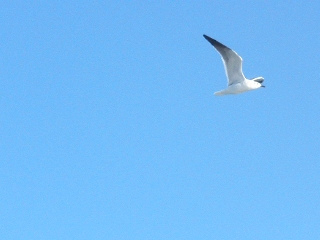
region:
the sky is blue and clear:
[19, 16, 232, 235]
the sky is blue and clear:
[40, 35, 150, 202]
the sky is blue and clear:
[76, 101, 136, 222]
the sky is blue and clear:
[139, 181, 160, 232]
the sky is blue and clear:
[104, 116, 168, 233]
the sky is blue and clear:
[114, 125, 149, 215]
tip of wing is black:
[200, 34, 228, 61]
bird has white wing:
[199, 24, 239, 88]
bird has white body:
[212, 78, 262, 102]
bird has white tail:
[215, 88, 234, 103]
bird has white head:
[248, 75, 261, 93]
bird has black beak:
[259, 83, 263, 88]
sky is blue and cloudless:
[7, 0, 49, 74]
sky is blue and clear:
[6, 4, 49, 79]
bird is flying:
[192, 34, 267, 99]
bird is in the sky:
[201, 34, 265, 100]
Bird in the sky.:
[191, 24, 269, 100]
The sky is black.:
[92, 144, 171, 196]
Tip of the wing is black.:
[200, 30, 232, 58]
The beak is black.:
[254, 80, 269, 92]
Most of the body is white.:
[216, 64, 257, 102]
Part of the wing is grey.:
[217, 49, 242, 73]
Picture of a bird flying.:
[1, 2, 319, 238]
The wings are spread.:
[196, 29, 273, 115]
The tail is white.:
[213, 82, 229, 101]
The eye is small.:
[249, 74, 269, 95]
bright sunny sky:
[5, 3, 195, 235]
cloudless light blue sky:
[3, 0, 196, 233]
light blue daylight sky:
[5, 3, 197, 227]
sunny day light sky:
[1, 2, 190, 231]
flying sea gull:
[187, 16, 274, 112]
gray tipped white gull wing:
[194, 27, 243, 78]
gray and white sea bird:
[185, 24, 269, 102]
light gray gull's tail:
[206, 80, 231, 112]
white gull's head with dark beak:
[246, 68, 265, 94]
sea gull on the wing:
[191, 26, 270, 105]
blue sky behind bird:
[166, 18, 288, 146]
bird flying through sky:
[176, 16, 295, 176]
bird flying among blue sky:
[165, 21, 282, 153]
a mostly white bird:
[176, 18, 288, 124]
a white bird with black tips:
[145, 16, 309, 148]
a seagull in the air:
[144, 16, 272, 119]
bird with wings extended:
[176, 16, 288, 115]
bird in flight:
[160, 16, 272, 128]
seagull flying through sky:
[146, 20, 265, 121]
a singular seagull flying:
[180, 26, 309, 143]